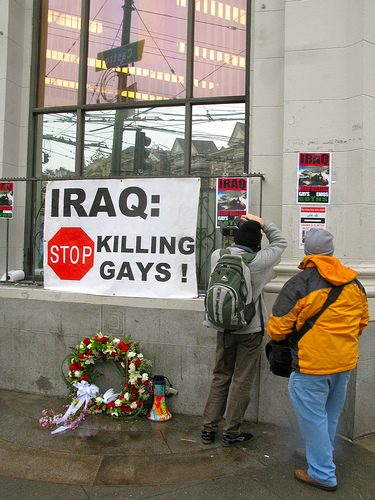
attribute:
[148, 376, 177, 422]
microphone — colorful, multi-colored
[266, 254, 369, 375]
jacket — orange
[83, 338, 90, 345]
flower — red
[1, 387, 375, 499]
floor — here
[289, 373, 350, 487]
pants — blue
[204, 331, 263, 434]
pants — brown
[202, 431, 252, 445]
shoes — black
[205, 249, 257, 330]
bag — behind, grey, green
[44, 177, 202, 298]
board — white, large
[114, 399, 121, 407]
flower — white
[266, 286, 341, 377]
bag — black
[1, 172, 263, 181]
railing — metal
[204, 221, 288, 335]
shirt — grey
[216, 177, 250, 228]
paper — hanging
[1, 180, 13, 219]
paper — hanging